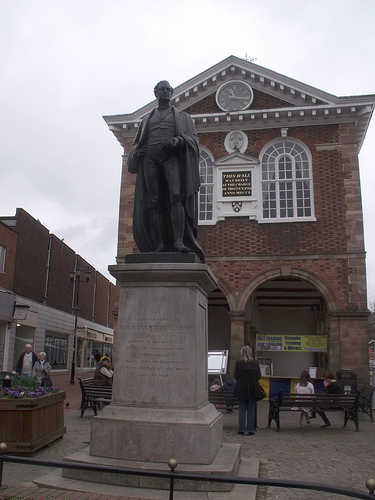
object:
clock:
[214, 75, 256, 119]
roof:
[126, 50, 348, 121]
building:
[82, 47, 375, 410]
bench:
[266, 389, 363, 433]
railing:
[1, 438, 373, 499]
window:
[255, 136, 317, 220]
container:
[1, 388, 66, 455]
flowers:
[1, 384, 7, 391]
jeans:
[239, 387, 257, 434]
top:
[164, 456, 179, 471]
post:
[167, 468, 178, 499]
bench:
[206, 388, 239, 410]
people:
[292, 368, 315, 394]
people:
[210, 375, 221, 392]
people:
[97, 357, 110, 379]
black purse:
[258, 387, 267, 401]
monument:
[105, 253, 220, 457]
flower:
[21, 392, 25, 395]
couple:
[17, 340, 57, 393]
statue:
[123, 79, 205, 262]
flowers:
[37, 385, 43, 392]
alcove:
[246, 286, 325, 401]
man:
[15, 342, 38, 381]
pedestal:
[77, 258, 265, 496]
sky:
[16, 4, 349, 56]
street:
[0, 341, 99, 440]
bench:
[360, 378, 373, 423]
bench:
[77, 376, 110, 414]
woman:
[235, 343, 266, 440]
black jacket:
[232, 360, 266, 404]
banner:
[254, 332, 327, 351]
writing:
[284, 335, 300, 352]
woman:
[31, 347, 54, 391]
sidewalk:
[55, 370, 83, 406]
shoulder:
[247, 357, 259, 367]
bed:
[7, 386, 64, 453]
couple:
[294, 367, 343, 426]